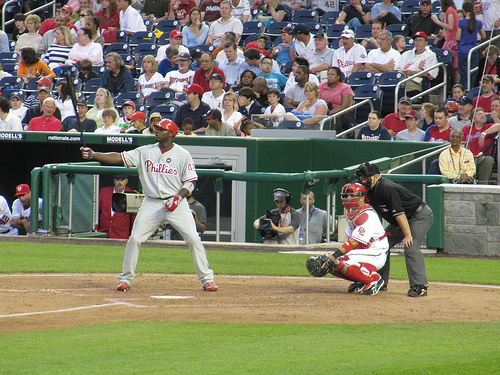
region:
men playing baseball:
[93, 84, 443, 302]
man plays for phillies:
[131, 147, 196, 190]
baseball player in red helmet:
[155, 116, 177, 147]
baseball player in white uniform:
[111, 112, 199, 299]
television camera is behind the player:
[103, 186, 154, 248]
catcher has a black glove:
[305, 169, 397, 297]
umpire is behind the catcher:
[356, 162, 438, 307]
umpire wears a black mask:
[352, 158, 404, 204]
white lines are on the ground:
[34, 274, 208, 346]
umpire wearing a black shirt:
[376, 180, 422, 215]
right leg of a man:
[118, 245, 133, 292]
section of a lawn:
[341, 333, 365, 334]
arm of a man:
[398, 215, 401, 233]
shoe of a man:
[373, 277, 378, 287]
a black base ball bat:
[62, 73, 82, 138]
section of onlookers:
[240, 77, 288, 103]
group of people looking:
[383, 87, 418, 113]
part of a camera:
[258, 207, 285, 227]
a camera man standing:
[270, 190, 285, 235]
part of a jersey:
[158, 158, 166, 163]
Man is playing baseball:
[53, 65, 223, 301]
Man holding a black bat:
[56, 67, 110, 183]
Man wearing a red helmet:
[137, 112, 195, 136]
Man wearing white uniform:
[111, 137, 219, 305]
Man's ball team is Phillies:
[127, 142, 195, 186]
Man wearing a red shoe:
[195, 273, 231, 297]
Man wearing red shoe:
[110, 275, 145, 297]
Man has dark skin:
[139, 120, 196, 152]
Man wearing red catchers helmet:
[318, 170, 378, 226]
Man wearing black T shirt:
[366, 175, 448, 231]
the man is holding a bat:
[56, 67, 218, 272]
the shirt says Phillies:
[125, 151, 196, 205]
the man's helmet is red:
[138, 108, 183, 138]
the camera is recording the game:
[107, 185, 146, 218]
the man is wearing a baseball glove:
[282, 227, 370, 282]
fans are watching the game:
[0, 0, 494, 177]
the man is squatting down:
[310, 176, 385, 304]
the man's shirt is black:
[363, 176, 423, 228]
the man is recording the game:
[255, 185, 301, 250]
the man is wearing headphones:
[260, 177, 297, 217]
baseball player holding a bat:
[131, 120, 188, 291]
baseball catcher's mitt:
[306, 253, 333, 274]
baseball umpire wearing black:
[370, 164, 430, 294]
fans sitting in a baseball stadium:
[21, 3, 494, 124]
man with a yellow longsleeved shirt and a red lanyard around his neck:
[438, 132, 470, 177]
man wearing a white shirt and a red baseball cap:
[408, 32, 433, 73]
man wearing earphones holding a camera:
[261, 187, 293, 236]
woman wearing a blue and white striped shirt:
[53, 27, 66, 59]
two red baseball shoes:
[117, 282, 219, 291]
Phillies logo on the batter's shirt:
[142, 158, 178, 175]